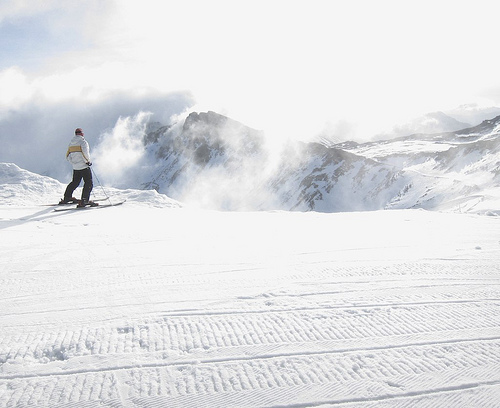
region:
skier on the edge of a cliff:
[44, 129, 124, 211]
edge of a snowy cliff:
[9, 186, 499, 248]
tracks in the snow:
[8, 296, 498, 398]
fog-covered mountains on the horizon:
[106, 110, 497, 210]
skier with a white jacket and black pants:
[40, 129, 124, 211]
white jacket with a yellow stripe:
[65, 138, 91, 170]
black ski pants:
[59, 169, 92, 199]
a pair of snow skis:
[43, 199, 125, 212]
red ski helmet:
[72, 130, 82, 136]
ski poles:
[91, 171, 111, 201]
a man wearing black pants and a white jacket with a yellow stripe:
[54, 122, 123, 217]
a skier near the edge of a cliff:
[33, 123, 130, 218]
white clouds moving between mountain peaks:
[94, 114, 299, 212]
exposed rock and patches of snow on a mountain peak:
[132, 108, 397, 200]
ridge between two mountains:
[25, 126, 407, 212]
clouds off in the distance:
[1, 68, 149, 175]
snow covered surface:
[2, 202, 498, 407]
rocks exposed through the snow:
[373, 104, 497, 173]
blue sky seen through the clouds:
[3, 10, 90, 90]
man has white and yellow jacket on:
[35, 125, 129, 212]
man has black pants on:
[37, 122, 128, 212]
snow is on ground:
[0, 98, 497, 406]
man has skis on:
[32, 122, 130, 214]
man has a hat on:
[35, 123, 127, 212]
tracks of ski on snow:
[0, 299, 499, 401]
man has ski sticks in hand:
[34, 125, 130, 212]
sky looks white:
[2, 0, 499, 135]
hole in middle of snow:
[3, 91, 493, 218]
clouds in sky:
[1, 1, 497, 131]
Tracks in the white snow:
[1, 291, 498, 406]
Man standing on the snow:
[58, 127, 100, 211]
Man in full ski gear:
[33, 124, 132, 211]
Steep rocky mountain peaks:
[0, 98, 497, 221]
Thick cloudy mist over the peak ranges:
[0, 0, 496, 212]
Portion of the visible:
[2, 0, 207, 118]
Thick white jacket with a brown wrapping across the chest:
[66, 135, 93, 170]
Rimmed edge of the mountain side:
[201, 111, 395, 176]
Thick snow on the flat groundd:
[0, 195, 499, 406]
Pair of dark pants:
[61, 165, 95, 208]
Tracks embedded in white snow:
[0, 299, 499, 406]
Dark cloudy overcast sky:
[2, 5, 497, 183]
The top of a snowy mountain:
[1, 0, 494, 407]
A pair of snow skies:
[39, 196, 125, 213]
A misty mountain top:
[106, 107, 351, 204]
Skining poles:
[88, 163, 113, 202]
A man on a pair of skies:
[40, 129, 123, 208]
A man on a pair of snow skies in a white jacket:
[42, 129, 126, 209]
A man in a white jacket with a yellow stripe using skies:
[44, 129, 121, 213]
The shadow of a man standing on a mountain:
[0, 200, 82, 231]